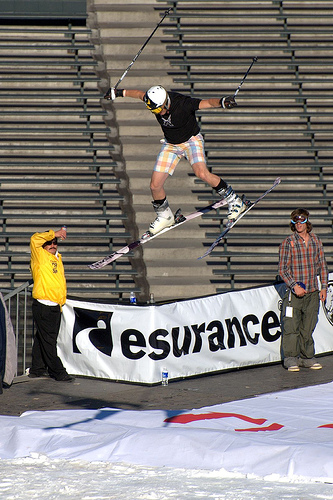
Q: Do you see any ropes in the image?
A: No, there are no ropes.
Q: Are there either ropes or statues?
A: No, there are no ropes or statues.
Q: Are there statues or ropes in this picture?
A: No, there are no ropes or statues.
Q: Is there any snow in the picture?
A: Yes, there is snow.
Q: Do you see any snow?
A: Yes, there is snow.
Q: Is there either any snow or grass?
A: Yes, there is snow.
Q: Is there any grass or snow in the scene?
A: Yes, there is snow.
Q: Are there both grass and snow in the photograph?
A: No, there is snow but no grass.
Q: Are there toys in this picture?
A: No, there are no toys.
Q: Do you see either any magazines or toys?
A: No, there are no toys or magazines.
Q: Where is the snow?
A: The snow is on the ground.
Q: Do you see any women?
A: No, there are no women.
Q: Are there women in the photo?
A: No, there are no women.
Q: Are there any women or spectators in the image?
A: No, there are no women or spectators.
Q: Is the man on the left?
A: Yes, the man is on the left of the image.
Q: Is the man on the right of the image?
A: No, the man is on the left of the image.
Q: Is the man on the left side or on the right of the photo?
A: The man is on the left of the image.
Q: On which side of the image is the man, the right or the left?
A: The man is on the left of the image.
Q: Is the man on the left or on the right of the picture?
A: The man is on the left of the image.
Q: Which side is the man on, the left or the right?
A: The man is on the left of the image.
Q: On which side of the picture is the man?
A: The man is on the left of the image.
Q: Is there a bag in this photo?
A: No, there are no bags.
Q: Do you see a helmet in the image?
A: Yes, there is a helmet.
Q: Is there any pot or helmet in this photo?
A: Yes, there is a helmet.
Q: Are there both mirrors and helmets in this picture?
A: No, there is a helmet but no mirrors.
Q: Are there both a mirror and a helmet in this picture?
A: No, there is a helmet but no mirrors.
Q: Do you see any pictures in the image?
A: No, there are no pictures.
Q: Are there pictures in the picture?
A: No, there are no pictures.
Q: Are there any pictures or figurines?
A: No, there are no pictures or figurines.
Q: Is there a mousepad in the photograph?
A: No, there are no mouse pads.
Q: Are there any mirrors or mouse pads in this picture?
A: No, there are no mouse pads or mirrors.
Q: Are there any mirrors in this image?
A: No, there are no mirrors.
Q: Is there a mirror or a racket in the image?
A: No, there are no mirrors or rackets.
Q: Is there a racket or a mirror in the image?
A: No, there are no mirrors or rackets.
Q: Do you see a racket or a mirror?
A: No, there are no mirrors or rackets.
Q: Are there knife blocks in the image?
A: No, there are no knife blocks.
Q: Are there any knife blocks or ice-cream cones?
A: No, there are no knife blocks or ice-cream cones.